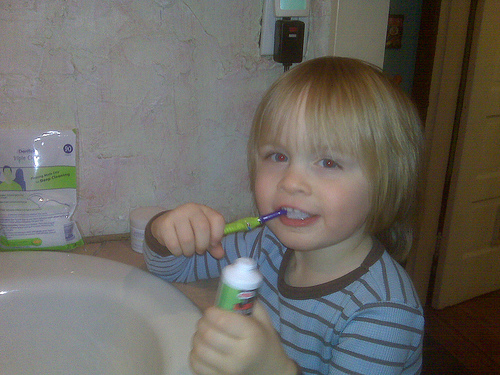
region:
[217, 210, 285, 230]
The toothbrush in the kid's hand.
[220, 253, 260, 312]
The tube of toothpaste.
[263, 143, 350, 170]
The eyes of the kid.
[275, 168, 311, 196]
The nose of the kid.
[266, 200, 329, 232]
The mouth of the kid.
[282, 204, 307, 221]
The teeth of the kid.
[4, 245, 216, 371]
The sink in front of the kid.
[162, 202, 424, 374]
The striped shirt the kid is wearing.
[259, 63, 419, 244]
The kid's blonde hair.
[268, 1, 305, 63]
The electrical socket above the kid's head.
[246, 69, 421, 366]
A small boy brushing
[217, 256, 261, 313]
A green and white toothpaste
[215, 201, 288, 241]
A small green tooth brush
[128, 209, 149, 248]
A small plastic fat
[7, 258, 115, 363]
A white bathroom sink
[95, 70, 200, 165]
A multi colored wall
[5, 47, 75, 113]
A multi colored wall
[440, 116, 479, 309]
A wooden bathroom door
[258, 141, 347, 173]
A Shiny little eyes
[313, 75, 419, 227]
A brown long hair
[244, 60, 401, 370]
child wearing a brown and blue striped shirt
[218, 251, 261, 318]
tube of toothpaste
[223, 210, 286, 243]
green and purple toothbrush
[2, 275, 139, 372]
white bathroom sink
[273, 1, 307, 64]
electrical outlet on the bathroom wall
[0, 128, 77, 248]
package of floss picks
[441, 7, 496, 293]
white door to the right of the child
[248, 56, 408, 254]
child with blond hair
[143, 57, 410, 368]
child holding a toothbrush and toothpaste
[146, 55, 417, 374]
child by a bathroom sink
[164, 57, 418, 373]
The boy is young.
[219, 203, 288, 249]
The tooth brush is blue.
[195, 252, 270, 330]
He is holding the tooth paste.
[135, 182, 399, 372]
The shirt is blue.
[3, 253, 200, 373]
The sink is white.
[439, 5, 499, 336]
The door is white.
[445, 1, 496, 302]
The door is open.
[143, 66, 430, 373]
The boy is brushing his teeth.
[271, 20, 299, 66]
The plug is black.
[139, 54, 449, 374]
Child standing in front of sink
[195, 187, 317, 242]
Toothbrush in child's mouth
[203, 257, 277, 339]
Toothpaste in child's hand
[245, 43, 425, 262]
Blonde hair on child's head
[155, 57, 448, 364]
Child wearing a striped shirt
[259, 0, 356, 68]
White socket on wall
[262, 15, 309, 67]
Black plug in socket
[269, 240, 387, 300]
Brown collar around shirt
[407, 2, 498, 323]
Doorway behind the child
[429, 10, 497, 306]
White wooden door